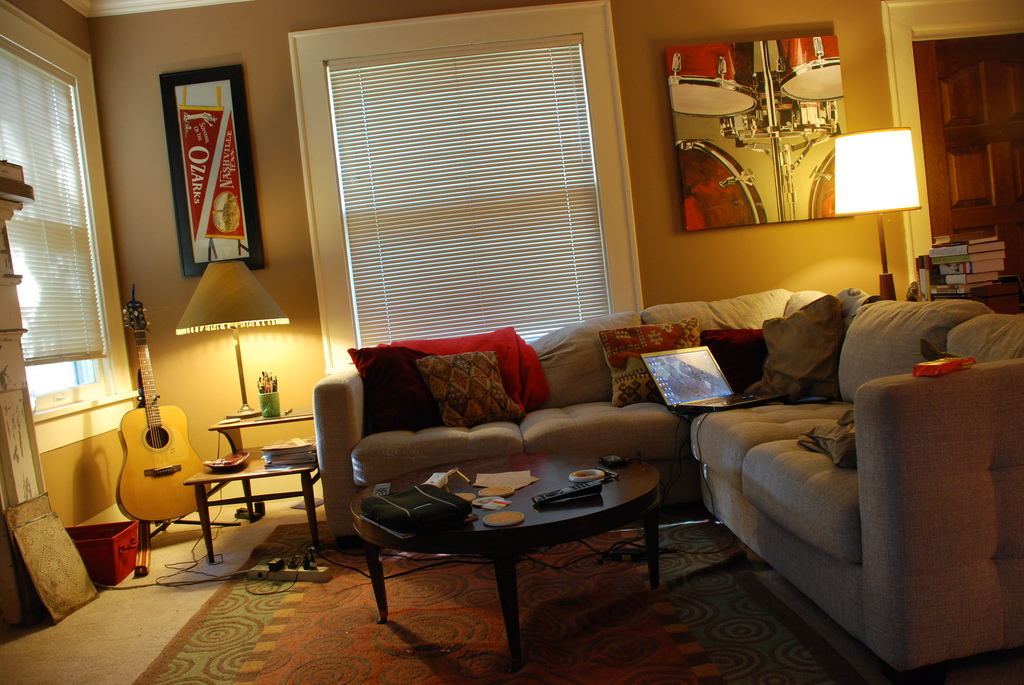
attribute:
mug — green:
[200, 359, 319, 424]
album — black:
[354, 465, 491, 526]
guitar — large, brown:
[112, 287, 208, 521]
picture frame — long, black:
[153, 58, 274, 281]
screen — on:
[639, 344, 735, 412]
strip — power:
[228, 547, 337, 584]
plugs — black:
[256, 552, 300, 578]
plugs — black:
[283, 552, 297, 572]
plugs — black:
[295, 547, 334, 573]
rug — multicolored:
[133, 497, 879, 681]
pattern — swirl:
[256, 539, 714, 680]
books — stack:
[920, 221, 1009, 295]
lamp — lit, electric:
[170, 240, 298, 346]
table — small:
[205, 394, 326, 444]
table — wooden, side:
[192, 385, 339, 573]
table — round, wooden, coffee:
[360, 452, 700, 673]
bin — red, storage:
[58, 502, 158, 595]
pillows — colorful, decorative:
[334, 325, 561, 429]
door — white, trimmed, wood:
[874, 5, 991, 291]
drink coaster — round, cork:
[474, 504, 535, 535]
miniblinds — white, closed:
[327, 33, 621, 368]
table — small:
[215, 405, 330, 527]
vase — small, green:
[248, 368, 287, 420]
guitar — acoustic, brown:
[105, 284, 226, 535]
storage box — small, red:
[55, 517, 155, 587]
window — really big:
[321, 31, 618, 354]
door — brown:
[917, 37, 993, 306]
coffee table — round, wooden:
[345, 443, 672, 675]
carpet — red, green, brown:
[137, 517, 905, 680]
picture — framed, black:
[146, 57, 276, 282]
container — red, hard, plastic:
[62, 515, 151, 589]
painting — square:
[660, 26, 859, 245]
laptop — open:
[632, 342, 792, 412]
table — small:
[204, 404, 347, 532]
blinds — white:
[328, 40, 609, 349]